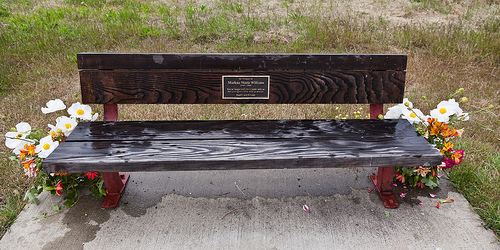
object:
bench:
[44, 53, 445, 209]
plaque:
[220, 74, 272, 99]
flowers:
[383, 97, 467, 191]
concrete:
[0, 167, 499, 249]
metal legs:
[365, 167, 399, 209]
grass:
[0, 0, 499, 53]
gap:
[83, 103, 406, 121]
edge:
[43, 149, 95, 167]